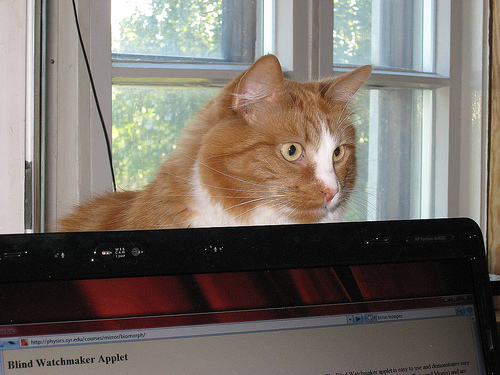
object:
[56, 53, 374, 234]
cat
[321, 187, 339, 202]
nose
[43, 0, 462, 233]
window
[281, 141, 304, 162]
eye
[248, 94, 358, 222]
face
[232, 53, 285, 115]
ear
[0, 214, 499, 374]
border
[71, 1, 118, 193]
wire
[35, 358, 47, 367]
words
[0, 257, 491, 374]
computer screen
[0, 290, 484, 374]
webpage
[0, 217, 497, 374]
computer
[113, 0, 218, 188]
tree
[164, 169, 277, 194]
whisker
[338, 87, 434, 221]
window pane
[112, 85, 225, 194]
window pane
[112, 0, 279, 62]
window pane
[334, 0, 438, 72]
window pane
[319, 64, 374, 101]
ear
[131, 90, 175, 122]
leaves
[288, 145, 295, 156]
pupil